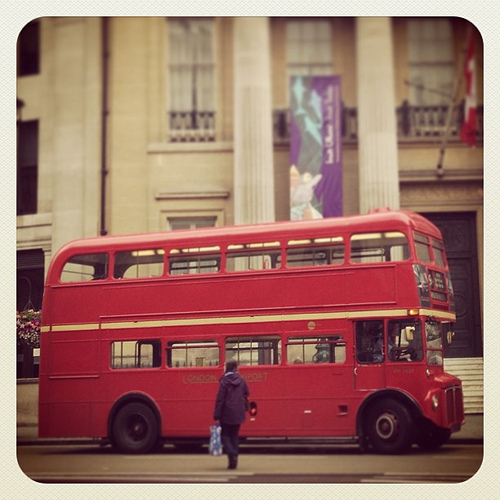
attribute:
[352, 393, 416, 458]
wheel — round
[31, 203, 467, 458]
bus — double decker, red, parked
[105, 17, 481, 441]
building — light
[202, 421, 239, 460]
bag — shopping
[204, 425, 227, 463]
bag — blue, shopping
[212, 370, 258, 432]
coat — large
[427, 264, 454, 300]
sign — black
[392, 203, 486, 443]
front — bus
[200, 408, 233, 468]
bag — blue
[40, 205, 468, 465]
view — side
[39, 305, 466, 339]
line — long, yellow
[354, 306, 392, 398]
door — dark brown